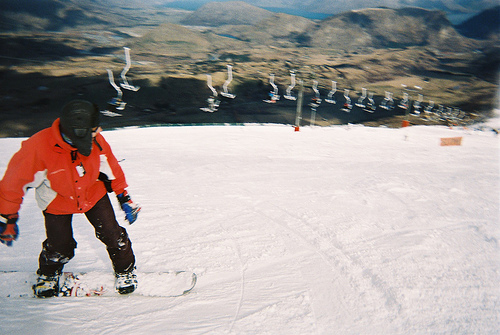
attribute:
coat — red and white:
[11, 127, 128, 230]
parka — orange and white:
[1, 117, 149, 227]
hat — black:
[56, 103, 101, 150]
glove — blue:
[120, 193, 143, 225]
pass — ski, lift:
[72, 161, 88, 176]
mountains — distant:
[2, 2, 488, 59]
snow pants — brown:
[45, 222, 125, 262]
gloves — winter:
[115, 183, 142, 223]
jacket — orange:
[20, 141, 123, 207]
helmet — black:
[50, 95, 102, 141]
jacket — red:
[4, 123, 144, 224]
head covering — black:
[61, 99, 93, 159]